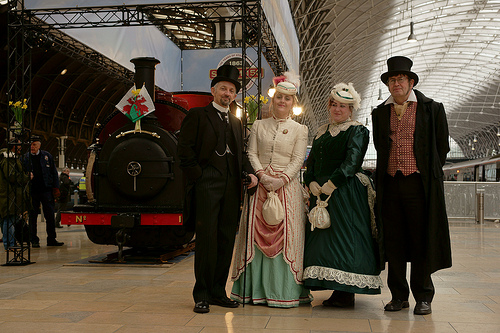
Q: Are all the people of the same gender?
A: No, they are both male and female.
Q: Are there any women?
A: Yes, there are women.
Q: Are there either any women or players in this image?
A: Yes, there are women.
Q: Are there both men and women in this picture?
A: Yes, there are both women and men.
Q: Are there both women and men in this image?
A: Yes, there are both women and men.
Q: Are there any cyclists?
A: No, there are no cyclists.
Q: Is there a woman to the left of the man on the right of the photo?
A: Yes, there are women to the left of the man.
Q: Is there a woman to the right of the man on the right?
A: No, the women are to the left of the man.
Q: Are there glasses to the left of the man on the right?
A: No, there are women to the left of the man.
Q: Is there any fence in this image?
A: No, there are no fences.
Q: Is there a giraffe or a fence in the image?
A: No, there are no fences or giraffes.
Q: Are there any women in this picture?
A: Yes, there is a woman.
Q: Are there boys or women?
A: Yes, there is a woman.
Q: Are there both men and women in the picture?
A: Yes, there are both a woman and a man.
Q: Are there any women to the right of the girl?
A: Yes, there is a woman to the right of the girl.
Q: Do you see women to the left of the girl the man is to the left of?
A: No, the woman is to the right of the girl.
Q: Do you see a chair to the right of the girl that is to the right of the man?
A: No, there is a woman to the right of the girl.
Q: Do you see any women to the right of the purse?
A: Yes, there is a woman to the right of the purse.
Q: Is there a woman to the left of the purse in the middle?
A: No, the woman is to the right of the purse.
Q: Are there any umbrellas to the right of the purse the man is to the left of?
A: No, there is a woman to the right of the purse.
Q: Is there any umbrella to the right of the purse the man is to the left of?
A: No, there is a woman to the right of the purse.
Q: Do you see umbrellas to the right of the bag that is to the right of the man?
A: No, there is a woman to the right of the purse.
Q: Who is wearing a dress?
A: The woman is wearing a dress.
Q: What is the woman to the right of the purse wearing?
A: The woman is wearing a dress.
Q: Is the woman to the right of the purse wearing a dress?
A: Yes, the woman is wearing a dress.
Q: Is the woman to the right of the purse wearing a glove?
A: No, the woman is wearing a dress.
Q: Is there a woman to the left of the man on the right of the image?
A: Yes, there is a woman to the left of the man.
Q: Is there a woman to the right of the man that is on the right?
A: No, the woman is to the left of the man.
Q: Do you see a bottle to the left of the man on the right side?
A: No, there is a woman to the left of the man.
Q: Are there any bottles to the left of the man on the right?
A: No, there is a woman to the left of the man.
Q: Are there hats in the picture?
A: Yes, there is a hat.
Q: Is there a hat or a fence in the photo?
A: Yes, there is a hat.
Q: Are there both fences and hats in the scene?
A: No, there is a hat but no fences.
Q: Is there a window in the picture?
A: Yes, there is a window.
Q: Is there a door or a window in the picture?
A: Yes, there is a window.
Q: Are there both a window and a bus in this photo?
A: No, there is a window but no buses.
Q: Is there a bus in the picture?
A: No, there are no buses.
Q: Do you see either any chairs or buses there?
A: No, there are no buses or chairs.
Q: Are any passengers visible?
A: No, there are no passengers.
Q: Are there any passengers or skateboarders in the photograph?
A: No, there are no passengers or skateboarders.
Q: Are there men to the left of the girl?
A: Yes, there is a man to the left of the girl.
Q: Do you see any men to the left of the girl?
A: Yes, there is a man to the left of the girl.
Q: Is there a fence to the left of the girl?
A: No, there is a man to the left of the girl.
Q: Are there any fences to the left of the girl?
A: No, there is a man to the left of the girl.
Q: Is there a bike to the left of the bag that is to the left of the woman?
A: No, there is a man to the left of the purse.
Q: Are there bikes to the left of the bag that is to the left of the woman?
A: No, there is a man to the left of the purse.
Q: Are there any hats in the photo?
A: Yes, there is a hat.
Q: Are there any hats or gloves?
A: Yes, there is a hat.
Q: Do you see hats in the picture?
A: Yes, there is a hat.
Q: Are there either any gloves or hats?
A: Yes, there is a hat.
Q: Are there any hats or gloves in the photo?
A: Yes, there is a hat.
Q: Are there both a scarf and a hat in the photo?
A: No, there is a hat but no scarves.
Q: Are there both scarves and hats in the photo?
A: No, there is a hat but no scarves.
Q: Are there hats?
A: Yes, there is a hat.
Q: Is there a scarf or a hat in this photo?
A: Yes, there is a hat.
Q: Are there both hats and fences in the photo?
A: No, there is a hat but no fences.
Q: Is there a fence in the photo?
A: No, there are no fences.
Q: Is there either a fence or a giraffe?
A: No, there are no fences or giraffes.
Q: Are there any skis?
A: No, there are no skis.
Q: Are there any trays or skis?
A: No, there are no skis or trays.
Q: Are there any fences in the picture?
A: No, there are no fences.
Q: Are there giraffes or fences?
A: No, there are no fences or giraffes.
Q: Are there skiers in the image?
A: No, there are no skiers.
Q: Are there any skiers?
A: No, there are no skiers.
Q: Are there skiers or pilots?
A: No, there are no skiers or pilots.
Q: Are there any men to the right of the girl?
A: Yes, there is a man to the right of the girl.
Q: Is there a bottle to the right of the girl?
A: No, there is a man to the right of the girl.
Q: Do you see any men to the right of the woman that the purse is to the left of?
A: Yes, there is a man to the right of the woman.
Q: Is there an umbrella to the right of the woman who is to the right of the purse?
A: No, there is a man to the right of the woman.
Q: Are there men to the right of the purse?
A: Yes, there is a man to the right of the purse.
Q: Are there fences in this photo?
A: No, there are no fences.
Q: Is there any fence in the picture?
A: No, there are no fences.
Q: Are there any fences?
A: No, there are no fences.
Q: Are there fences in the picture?
A: No, there are no fences.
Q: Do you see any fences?
A: No, there are no fences.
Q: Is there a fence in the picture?
A: No, there are no fences.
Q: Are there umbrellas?
A: No, there are no umbrellas.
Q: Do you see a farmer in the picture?
A: No, there are no farmers.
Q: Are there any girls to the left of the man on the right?
A: Yes, there is a girl to the left of the man.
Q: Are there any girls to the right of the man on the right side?
A: No, the girl is to the left of the man.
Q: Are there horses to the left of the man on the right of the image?
A: No, there is a girl to the left of the man.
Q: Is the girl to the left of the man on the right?
A: Yes, the girl is to the left of the man.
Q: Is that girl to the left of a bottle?
A: No, the girl is to the left of the man.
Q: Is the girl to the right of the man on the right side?
A: No, the girl is to the left of the man.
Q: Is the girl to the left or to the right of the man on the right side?
A: The girl is to the left of the man.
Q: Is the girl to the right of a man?
A: Yes, the girl is to the right of a man.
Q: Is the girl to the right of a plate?
A: No, the girl is to the right of a man.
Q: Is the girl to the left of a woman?
A: Yes, the girl is to the left of a woman.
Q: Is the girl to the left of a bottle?
A: No, the girl is to the left of a woman.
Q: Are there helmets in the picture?
A: No, there are no helmets.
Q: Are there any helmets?
A: No, there are no helmets.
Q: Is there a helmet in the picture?
A: No, there are no helmets.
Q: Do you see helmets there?
A: No, there are no helmets.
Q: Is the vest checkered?
A: Yes, the vest is checkered.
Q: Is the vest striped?
A: No, the vest is checkered.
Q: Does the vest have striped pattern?
A: No, the vest is checkered.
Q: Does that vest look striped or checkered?
A: The vest is checkered.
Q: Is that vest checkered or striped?
A: The vest is checkered.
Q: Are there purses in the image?
A: Yes, there is a purse.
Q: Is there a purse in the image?
A: Yes, there is a purse.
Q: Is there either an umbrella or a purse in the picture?
A: Yes, there is a purse.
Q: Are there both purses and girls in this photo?
A: Yes, there are both a purse and a girl.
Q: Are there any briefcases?
A: No, there are no briefcases.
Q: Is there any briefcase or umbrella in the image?
A: No, there are no briefcases or umbrellas.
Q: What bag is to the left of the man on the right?
A: The bag is a purse.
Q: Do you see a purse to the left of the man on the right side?
A: Yes, there is a purse to the left of the man.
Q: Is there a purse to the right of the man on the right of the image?
A: No, the purse is to the left of the man.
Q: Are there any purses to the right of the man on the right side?
A: No, the purse is to the left of the man.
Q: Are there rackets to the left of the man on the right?
A: No, there is a purse to the left of the man.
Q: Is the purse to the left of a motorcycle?
A: No, the purse is to the left of the man.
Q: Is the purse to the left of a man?
A: No, the purse is to the right of a man.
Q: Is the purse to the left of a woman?
A: Yes, the purse is to the left of a woman.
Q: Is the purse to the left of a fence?
A: No, the purse is to the left of a woman.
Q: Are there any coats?
A: Yes, there is a coat.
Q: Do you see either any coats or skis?
A: Yes, there is a coat.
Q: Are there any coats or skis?
A: Yes, there is a coat.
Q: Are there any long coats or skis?
A: Yes, there is a long coat.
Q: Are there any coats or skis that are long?
A: Yes, the coat is long.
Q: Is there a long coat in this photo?
A: Yes, there is a long coat.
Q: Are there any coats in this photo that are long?
A: Yes, there is a coat that is long.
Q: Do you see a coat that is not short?
A: Yes, there is a long coat.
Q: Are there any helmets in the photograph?
A: No, there are no helmets.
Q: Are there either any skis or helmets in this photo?
A: No, there are no helmets or skis.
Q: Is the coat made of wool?
A: Yes, the coat is made of wool.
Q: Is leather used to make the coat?
A: No, the coat is made of wool.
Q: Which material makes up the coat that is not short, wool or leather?
A: The coat is made of wool.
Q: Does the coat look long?
A: Yes, the coat is long.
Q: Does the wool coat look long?
A: Yes, the coat is long.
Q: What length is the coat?
A: The coat is long.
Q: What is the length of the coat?
A: The coat is long.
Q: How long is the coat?
A: The coat is long.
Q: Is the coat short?
A: No, the coat is long.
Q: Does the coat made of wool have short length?
A: No, the coat is long.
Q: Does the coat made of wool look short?
A: No, the coat is long.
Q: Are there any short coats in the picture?
A: No, there is a coat but it is long.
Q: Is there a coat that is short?
A: No, there is a coat but it is long.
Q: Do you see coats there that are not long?
A: No, there is a coat but it is long.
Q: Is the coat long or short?
A: The coat is long.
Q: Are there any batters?
A: No, there are no batters.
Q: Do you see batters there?
A: No, there are no batters.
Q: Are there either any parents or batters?
A: No, there are no batters or parents.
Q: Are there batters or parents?
A: No, there are no batters or parents.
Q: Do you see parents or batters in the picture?
A: No, there are no batters or parents.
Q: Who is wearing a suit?
A: The man is wearing a suit.